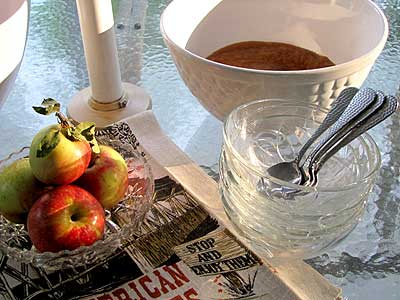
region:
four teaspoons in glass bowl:
[254, 85, 397, 194]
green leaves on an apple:
[34, 107, 98, 160]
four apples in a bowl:
[6, 141, 124, 242]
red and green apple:
[3, 188, 96, 261]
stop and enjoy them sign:
[167, 227, 260, 272]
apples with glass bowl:
[10, 143, 154, 270]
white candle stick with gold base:
[79, 8, 149, 158]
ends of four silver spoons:
[300, 84, 397, 150]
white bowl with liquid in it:
[155, 4, 383, 130]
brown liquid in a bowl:
[205, 35, 341, 97]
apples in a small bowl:
[2, 92, 152, 271]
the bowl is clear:
[0, 127, 168, 276]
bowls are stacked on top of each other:
[213, 88, 385, 270]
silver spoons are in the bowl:
[204, 86, 399, 265]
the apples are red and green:
[0, 92, 133, 257]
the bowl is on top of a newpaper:
[3, 108, 344, 298]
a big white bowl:
[152, 2, 399, 127]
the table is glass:
[1, 0, 398, 298]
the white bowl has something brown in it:
[156, 1, 389, 139]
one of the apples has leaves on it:
[26, 93, 102, 182]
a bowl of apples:
[9, 84, 194, 262]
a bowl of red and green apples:
[8, 86, 174, 288]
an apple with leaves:
[19, 77, 120, 213]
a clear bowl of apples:
[0, 106, 173, 273]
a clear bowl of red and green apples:
[15, 113, 163, 297]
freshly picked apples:
[8, 100, 157, 260]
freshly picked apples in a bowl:
[8, 105, 175, 299]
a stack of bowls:
[186, 80, 390, 299]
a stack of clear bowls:
[202, 68, 395, 273]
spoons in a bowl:
[199, 40, 396, 268]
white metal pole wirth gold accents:
[64, 2, 154, 131]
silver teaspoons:
[258, 87, 394, 197]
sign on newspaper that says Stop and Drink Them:
[172, 225, 261, 297]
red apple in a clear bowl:
[26, 185, 104, 251]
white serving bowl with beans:
[160, 1, 386, 132]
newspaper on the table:
[3, 112, 338, 296]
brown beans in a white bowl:
[203, 40, 332, 76]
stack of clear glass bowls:
[219, 96, 379, 265]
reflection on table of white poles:
[116, 2, 145, 80]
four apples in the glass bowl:
[7, 116, 138, 250]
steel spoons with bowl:
[270, 86, 340, 206]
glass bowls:
[226, 114, 330, 246]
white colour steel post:
[76, 3, 127, 101]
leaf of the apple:
[39, 100, 56, 114]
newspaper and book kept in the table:
[144, 228, 226, 296]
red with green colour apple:
[36, 127, 89, 179]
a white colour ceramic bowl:
[162, 10, 388, 79]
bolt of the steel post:
[118, 97, 130, 109]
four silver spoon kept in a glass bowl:
[271, 81, 340, 205]